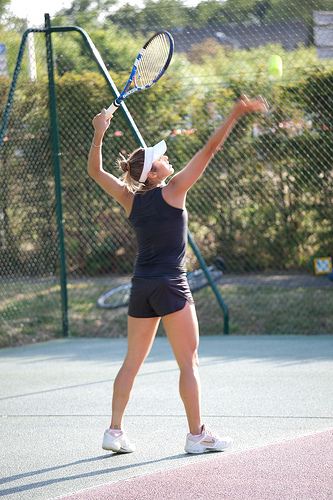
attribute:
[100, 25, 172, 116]
tennis racket — black, blue, white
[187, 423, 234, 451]
shoe — white, pink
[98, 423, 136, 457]
shoe — pink, white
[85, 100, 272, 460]
female — playing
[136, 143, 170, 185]
visor — white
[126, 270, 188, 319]
skirt — black, dark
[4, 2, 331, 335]
fencing — green, large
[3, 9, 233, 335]
poles — green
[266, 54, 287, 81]
tennis ball — yellow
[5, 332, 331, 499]
tennis court — brownish gray, gray, pink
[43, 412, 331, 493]
line — white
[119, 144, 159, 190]
hair — pulled back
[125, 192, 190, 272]
tank top — black